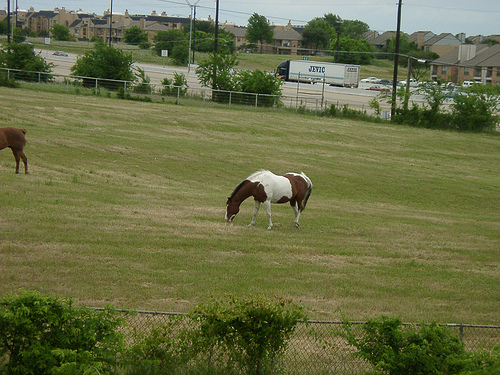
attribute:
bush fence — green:
[17, 303, 177, 372]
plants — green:
[1, 290, 498, 372]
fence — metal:
[219, 85, 264, 107]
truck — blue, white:
[275, 59, 360, 86]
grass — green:
[329, 139, 492, 306]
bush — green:
[192, 293, 324, 370]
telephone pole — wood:
[387, 0, 404, 127]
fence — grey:
[301, 329, 336, 364]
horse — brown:
[201, 156, 337, 251]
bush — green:
[371, 310, 473, 371]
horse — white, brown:
[220, 166, 316, 236]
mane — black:
[224, 176, 251, 203]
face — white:
[226, 195, 237, 227]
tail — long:
[304, 171, 316, 213]